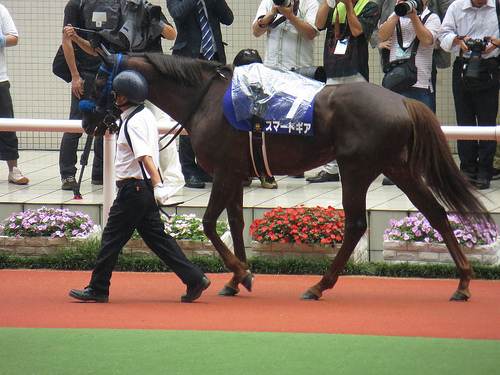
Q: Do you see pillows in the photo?
A: No, there are no pillows.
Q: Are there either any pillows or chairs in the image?
A: No, there are no pillows or chairs.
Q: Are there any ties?
A: Yes, there is a tie.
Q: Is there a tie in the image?
A: Yes, there is a tie.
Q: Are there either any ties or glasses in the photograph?
A: Yes, there is a tie.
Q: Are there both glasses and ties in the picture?
A: No, there is a tie but no glasses.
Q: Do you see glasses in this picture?
A: No, there are no glasses.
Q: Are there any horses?
A: Yes, there is a horse.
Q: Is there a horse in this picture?
A: Yes, there is a horse.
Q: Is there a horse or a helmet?
A: Yes, there is a horse.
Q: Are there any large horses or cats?
A: Yes, there is a large horse.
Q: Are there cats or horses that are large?
A: Yes, the horse is large.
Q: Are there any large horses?
A: Yes, there is a large horse.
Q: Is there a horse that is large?
A: Yes, there is a horse that is large.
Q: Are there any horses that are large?
A: Yes, there is a horse that is large.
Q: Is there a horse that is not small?
A: Yes, there is a large horse.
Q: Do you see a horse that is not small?
A: Yes, there is a large horse.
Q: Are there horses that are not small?
A: Yes, there is a large horse.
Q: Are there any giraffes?
A: No, there are no giraffes.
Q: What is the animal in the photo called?
A: The animal is a horse.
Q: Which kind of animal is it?
A: The animal is a horse.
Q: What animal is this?
A: This is a horse.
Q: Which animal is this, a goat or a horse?
A: This is a horse.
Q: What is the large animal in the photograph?
A: The animal is a horse.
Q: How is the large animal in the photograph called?
A: The animal is a horse.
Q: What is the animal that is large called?
A: The animal is a horse.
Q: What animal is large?
A: The animal is a horse.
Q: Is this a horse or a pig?
A: This is a horse.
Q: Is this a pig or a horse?
A: This is a horse.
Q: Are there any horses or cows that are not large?
A: No, there is a horse but it is large.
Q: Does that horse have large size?
A: Yes, the horse is large.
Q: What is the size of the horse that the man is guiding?
A: The horse is large.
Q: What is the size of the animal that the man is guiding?
A: The horse is large.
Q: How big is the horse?
A: The horse is large.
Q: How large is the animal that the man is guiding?
A: The horse is large.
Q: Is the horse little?
A: No, the horse is large.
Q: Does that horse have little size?
A: No, the horse is large.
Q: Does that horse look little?
A: No, the horse is large.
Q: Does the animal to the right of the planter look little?
A: No, the horse is large.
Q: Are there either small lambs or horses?
A: No, there is a horse but it is large.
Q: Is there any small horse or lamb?
A: No, there is a horse but it is large.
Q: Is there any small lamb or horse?
A: No, there is a horse but it is large.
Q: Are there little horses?
A: No, there is a horse but it is large.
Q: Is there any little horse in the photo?
A: No, there is a horse but it is large.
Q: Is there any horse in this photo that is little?
A: No, there is a horse but it is large.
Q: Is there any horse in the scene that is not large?
A: No, there is a horse but it is large.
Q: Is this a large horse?
A: Yes, this is a large horse.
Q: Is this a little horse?
A: No, this is a large horse.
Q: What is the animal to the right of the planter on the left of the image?
A: The animal is a horse.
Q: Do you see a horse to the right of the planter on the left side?
A: Yes, there is a horse to the right of the planter.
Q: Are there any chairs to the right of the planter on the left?
A: No, there is a horse to the right of the planter.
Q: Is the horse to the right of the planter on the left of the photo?
A: Yes, the horse is to the right of the planter.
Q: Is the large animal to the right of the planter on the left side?
A: Yes, the horse is to the right of the planter.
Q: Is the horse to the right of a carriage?
A: No, the horse is to the right of the planter.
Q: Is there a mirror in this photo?
A: No, there are no mirrors.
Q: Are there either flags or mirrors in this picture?
A: No, there are no mirrors or flags.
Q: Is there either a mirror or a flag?
A: No, there are no mirrors or flags.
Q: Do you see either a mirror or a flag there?
A: No, there are no mirrors or flags.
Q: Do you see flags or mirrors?
A: No, there are no mirrors or flags.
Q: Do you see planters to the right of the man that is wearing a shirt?
A: Yes, there is a planter to the right of the man.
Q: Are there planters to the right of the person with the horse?
A: Yes, there is a planter to the right of the man.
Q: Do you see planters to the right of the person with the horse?
A: Yes, there is a planter to the right of the man.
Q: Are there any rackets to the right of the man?
A: No, there is a planter to the right of the man.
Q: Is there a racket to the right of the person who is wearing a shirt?
A: No, there is a planter to the right of the man.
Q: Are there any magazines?
A: No, there are no magazines.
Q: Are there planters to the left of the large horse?
A: Yes, there is a planter to the left of the horse.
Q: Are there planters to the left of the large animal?
A: Yes, there is a planter to the left of the horse.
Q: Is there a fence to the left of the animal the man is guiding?
A: No, there is a planter to the left of the horse.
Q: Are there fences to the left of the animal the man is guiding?
A: No, there is a planter to the left of the horse.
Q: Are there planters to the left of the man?
A: Yes, there is a planter to the left of the man.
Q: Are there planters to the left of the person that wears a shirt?
A: Yes, there is a planter to the left of the man.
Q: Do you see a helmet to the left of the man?
A: No, there is a planter to the left of the man.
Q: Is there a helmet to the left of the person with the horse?
A: No, there is a planter to the left of the man.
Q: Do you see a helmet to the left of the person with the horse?
A: No, there is a planter to the left of the man.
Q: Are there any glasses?
A: No, there are no glasses.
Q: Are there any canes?
A: No, there are no canes.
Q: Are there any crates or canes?
A: No, there are no canes or crates.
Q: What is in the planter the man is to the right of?
A: The flowers are in the planter.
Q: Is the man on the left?
A: Yes, the man is on the left of the image.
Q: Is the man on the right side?
A: No, the man is on the left of the image.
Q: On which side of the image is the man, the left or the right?
A: The man is on the left of the image.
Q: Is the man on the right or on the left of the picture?
A: The man is on the left of the image.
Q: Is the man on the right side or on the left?
A: The man is on the left of the image.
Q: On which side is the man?
A: The man is on the left of the image.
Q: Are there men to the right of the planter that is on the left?
A: Yes, there is a man to the right of the planter.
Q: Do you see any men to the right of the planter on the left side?
A: Yes, there is a man to the right of the planter.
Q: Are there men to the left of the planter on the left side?
A: No, the man is to the right of the planter.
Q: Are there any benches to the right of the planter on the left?
A: No, there is a man to the right of the planter.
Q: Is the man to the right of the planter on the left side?
A: Yes, the man is to the right of the planter.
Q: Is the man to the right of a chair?
A: No, the man is to the right of the planter.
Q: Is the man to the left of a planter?
A: No, the man is to the right of a planter.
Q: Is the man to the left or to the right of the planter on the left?
A: The man is to the right of the planter.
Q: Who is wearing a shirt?
A: The man is wearing a shirt.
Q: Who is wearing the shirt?
A: The man is wearing a shirt.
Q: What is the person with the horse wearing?
A: The man is wearing a shirt.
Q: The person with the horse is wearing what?
A: The man is wearing a shirt.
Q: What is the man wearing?
A: The man is wearing a shirt.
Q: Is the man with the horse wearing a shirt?
A: Yes, the man is wearing a shirt.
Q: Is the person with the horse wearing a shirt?
A: Yes, the man is wearing a shirt.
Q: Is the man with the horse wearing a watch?
A: No, the man is wearing a shirt.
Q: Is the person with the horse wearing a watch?
A: No, the man is wearing a shirt.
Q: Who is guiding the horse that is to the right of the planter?
A: The man is guiding the horse.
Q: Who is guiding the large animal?
A: The man is guiding the horse.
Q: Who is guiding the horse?
A: The man is guiding the horse.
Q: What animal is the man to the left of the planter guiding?
A: The man is guiding the horse.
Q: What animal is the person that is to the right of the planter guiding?
A: The man is guiding the horse.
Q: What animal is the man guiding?
A: The man is guiding the horse.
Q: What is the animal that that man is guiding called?
A: The animal is a horse.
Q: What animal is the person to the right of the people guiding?
A: The man is guiding the horse.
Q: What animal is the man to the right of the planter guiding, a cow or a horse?
A: The man is guiding a horse.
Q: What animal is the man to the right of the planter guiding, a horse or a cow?
A: The man is guiding a horse.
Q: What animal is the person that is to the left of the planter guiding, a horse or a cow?
A: The man is guiding a horse.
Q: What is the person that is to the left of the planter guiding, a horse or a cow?
A: The man is guiding a horse.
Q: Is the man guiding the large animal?
A: Yes, the man is guiding the horse.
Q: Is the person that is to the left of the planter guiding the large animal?
A: Yes, the man is guiding the horse.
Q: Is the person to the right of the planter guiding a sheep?
A: No, the man is guiding the horse.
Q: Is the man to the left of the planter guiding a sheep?
A: No, the man is guiding the horse.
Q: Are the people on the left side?
A: Yes, the people are on the left of the image.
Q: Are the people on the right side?
A: No, the people are on the left of the image.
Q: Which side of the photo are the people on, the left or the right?
A: The people are on the left of the image.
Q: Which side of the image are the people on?
A: The people are on the left of the image.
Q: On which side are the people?
A: The people are on the left of the image.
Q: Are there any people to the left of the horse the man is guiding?
A: Yes, there are people to the left of the horse.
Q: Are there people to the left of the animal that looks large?
A: Yes, there are people to the left of the horse.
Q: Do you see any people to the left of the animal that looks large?
A: Yes, there are people to the left of the horse.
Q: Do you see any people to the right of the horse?
A: No, the people are to the left of the horse.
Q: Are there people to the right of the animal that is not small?
A: No, the people are to the left of the horse.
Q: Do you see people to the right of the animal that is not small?
A: No, the people are to the left of the horse.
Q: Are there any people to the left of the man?
A: Yes, there are people to the left of the man.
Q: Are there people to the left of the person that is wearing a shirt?
A: Yes, there are people to the left of the man.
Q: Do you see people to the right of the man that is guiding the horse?
A: No, the people are to the left of the man.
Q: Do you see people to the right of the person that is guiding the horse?
A: No, the people are to the left of the man.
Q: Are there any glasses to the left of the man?
A: No, there are people to the left of the man.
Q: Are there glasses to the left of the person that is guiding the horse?
A: No, there are people to the left of the man.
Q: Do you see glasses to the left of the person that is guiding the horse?
A: No, there are people to the left of the man.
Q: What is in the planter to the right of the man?
A: The flowers are in the planter.